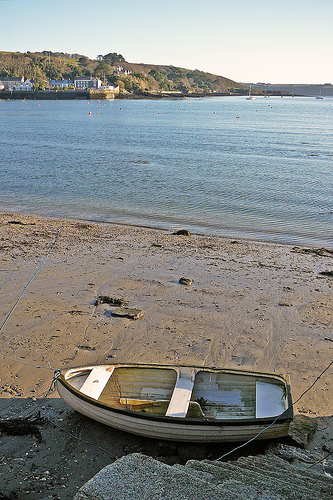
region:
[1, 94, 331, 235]
a large body of water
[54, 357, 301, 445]
a boat by the sea shore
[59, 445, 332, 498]
grey rocks at the beach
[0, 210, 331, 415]
wet sand and mud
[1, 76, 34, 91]
white building at the background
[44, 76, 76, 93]
white building at the background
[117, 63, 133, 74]
white building at the background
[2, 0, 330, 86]
there is a clear sky at the background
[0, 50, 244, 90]
a small mountain at the background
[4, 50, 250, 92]
trees dotted all over the mountain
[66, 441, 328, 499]
flight of concrete steps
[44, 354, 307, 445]
a small wooden boat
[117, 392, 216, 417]
the boat's oars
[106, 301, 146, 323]
a square shaped rock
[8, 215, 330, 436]
the wet sand of the beach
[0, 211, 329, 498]
a rocky, sandy, beach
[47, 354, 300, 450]
a small white rowboat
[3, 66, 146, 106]
buildings in the distance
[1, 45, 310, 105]
a large hill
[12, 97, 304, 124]
many red colored bouys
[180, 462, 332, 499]
Staircase to the beach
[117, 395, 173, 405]
Paddle in a small boat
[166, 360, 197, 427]
Seat in a small boat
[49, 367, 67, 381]
Rigging on a small boat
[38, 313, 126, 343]
Sand at the beach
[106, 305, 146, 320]
A rock in the sand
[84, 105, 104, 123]
Buoys in the water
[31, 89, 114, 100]
A large water retaining wall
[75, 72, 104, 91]
Large buildings in the background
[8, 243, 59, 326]
Rope line in the sand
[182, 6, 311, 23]
this is the sky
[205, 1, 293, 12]
the sky is blue in color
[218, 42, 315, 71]
the sky is bright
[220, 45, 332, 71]
the sky has some clouds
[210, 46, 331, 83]
the clouds are white in color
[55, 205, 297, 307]
this is a beach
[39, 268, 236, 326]
the sand is brown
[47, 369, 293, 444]
this is a boat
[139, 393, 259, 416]
the boat is wooden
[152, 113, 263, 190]
the water is blue in color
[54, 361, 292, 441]
small grounded wooden boat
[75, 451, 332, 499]
concrete steps to beach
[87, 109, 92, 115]
orange buoy in water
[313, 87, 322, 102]
sailboat in distance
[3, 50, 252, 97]
hill with trees beside water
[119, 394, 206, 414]
manual rudder on wooden boat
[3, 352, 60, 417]
rope holding grounded boat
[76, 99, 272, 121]
multiple orange buoys in water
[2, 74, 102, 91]
buildings behind seawall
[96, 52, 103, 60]
building on top of hill